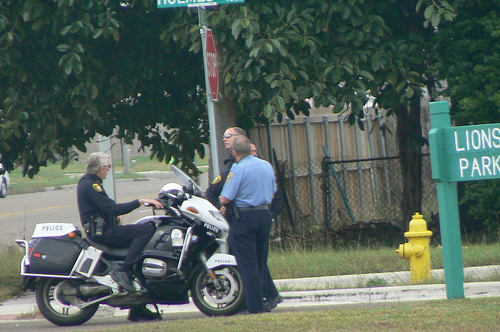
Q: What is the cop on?
A: A motorcycle.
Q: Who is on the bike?
A: Cop.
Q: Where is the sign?
A: On the right.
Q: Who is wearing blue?
A: A cop.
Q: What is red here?
A: Stop sign.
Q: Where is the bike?
A: On the street.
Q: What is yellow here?
A: Hydrant.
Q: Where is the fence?
A: By the tree.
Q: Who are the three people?
A: Cops.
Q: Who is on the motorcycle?
A: A policeman.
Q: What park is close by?
A: Lions Park.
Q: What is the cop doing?
A: Sitting on his bike.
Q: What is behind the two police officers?
A: A sign.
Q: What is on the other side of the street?
A: A fire hydrant.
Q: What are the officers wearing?
A: Uniforms.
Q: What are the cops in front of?
A: A stop sign.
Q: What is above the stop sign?
A: Street signs.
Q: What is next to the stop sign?
A: A fence.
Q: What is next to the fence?
A: Trees.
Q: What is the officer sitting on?
A: A motorcycle.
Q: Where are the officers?
A: In the street.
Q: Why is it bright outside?
A: Its daytime.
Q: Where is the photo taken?
A: Park.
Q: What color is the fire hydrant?
A: Yellow.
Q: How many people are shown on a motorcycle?
A: One.